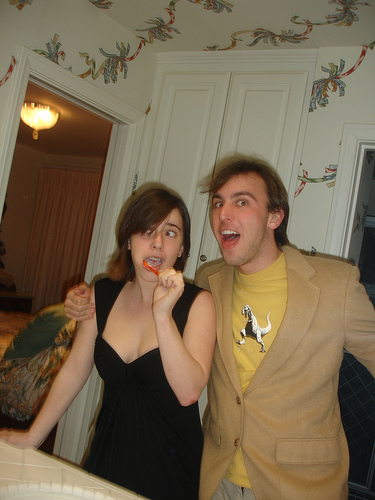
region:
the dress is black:
[98, 280, 197, 498]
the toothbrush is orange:
[141, 261, 163, 280]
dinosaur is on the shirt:
[237, 304, 275, 354]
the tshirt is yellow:
[246, 278, 280, 309]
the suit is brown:
[201, 264, 374, 499]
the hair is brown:
[132, 189, 172, 217]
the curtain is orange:
[35, 178, 90, 269]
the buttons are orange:
[230, 394, 249, 451]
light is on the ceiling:
[26, 104, 53, 143]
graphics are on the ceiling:
[84, 6, 210, 44]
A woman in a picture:
[200, 149, 345, 492]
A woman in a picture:
[90, 191, 197, 496]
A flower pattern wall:
[298, 152, 345, 210]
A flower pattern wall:
[295, 67, 346, 112]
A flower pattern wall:
[84, 68, 127, 87]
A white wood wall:
[160, 74, 226, 151]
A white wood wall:
[142, 151, 204, 190]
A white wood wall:
[293, 187, 334, 243]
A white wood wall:
[235, 81, 311, 157]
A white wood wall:
[311, 117, 346, 157]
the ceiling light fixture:
[20, 101, 59, 138]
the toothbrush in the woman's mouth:
[142, 258, 158, 275]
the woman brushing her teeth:
[0, 187, 215, 498]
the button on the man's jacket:
[234, 438, 239, 447]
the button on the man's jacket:
[235, 396, 240, 405]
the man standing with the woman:
[193, 154, 374, 499]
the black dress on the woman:
[82, 277, 203, 498]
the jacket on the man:
[192, 243, 373, 498]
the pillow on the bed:
[3, 303, 71, 358]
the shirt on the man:
[224, 250, 287, 489]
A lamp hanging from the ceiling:
[22, 101, 58, 140]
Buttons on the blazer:
[232, 395, 240, 447]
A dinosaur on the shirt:
[236, 303, 272, 350]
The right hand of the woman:
[1, 429, 39, 448]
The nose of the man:
[218, 205, 232, 221]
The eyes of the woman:
[143, 227, 176, 236]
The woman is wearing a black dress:
[80, 276, 202, 499]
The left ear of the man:
[267, 208, 283, 228]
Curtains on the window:
[21, 164, 101, 313]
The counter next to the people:
[1, 436, 144, 499]